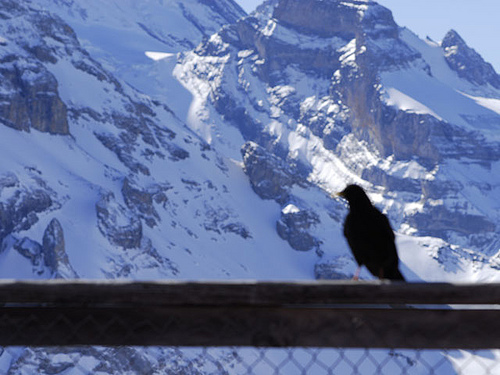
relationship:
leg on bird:
[353, 265, 361, 276] [338, 175, 418, 269]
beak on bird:
[335, 192, 340, 196] [322, 185, 415, 294]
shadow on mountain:
[110, 73, 210, 173] [75, 30, 491, 242]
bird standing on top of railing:
[333, 180, 409, 283] [0, 278, 484, 351]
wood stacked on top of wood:
[1, 278, 484, 306] [1, 304, 484, 349]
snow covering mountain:
[1, 1, 484, 371] [1, 2, 483, 371]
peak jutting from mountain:
[191, 1, 420, 88] [1, 2, 483, 371]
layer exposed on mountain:
[204, 18, 420, 213] [1, 2, 483, 371]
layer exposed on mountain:
[228, 18, 339, 76] [1, 2, 483, 371]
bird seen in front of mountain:
[333, 183, 408, 283] [1, 2, 483, 371]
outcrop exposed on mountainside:
[2, 165, 51, 243] [2, 2, 484, 372]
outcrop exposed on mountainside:
[40, 215, 78, 277] [2, 2, 484, 372]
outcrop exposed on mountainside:
[89, 185, 144, 247] [2, 2, 484, 372]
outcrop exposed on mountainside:
[1, 38, 71, 136] [2, 2, 484, 372]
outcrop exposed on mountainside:
[119, 173, 163, 228] [2, 2, 484, 372]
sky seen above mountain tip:
[233, 1, 484, 70] [187, 1, 434, 86]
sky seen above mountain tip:
[233, 1, 484, 70] [438, 26, 485, 86]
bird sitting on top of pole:
[333, 180, 409, 283] [1, 276, 484, 349]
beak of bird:
[335, 192, 340, 196] [333, 180, 409, 283]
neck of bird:
[338, 194, 372, 207] [333, 180, 409, 283]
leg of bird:
[350, 260, 365, 285] [334, 183, 405, 291]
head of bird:
[338, 181, 365, 200] [334, 183, 405, 291]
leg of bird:
[353, 265, 361, 276] [334, 183, 405, 291]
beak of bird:
[335, 192, 340, 196] [334, 183, 405, 291]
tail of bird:
[384, 267, 405, 285] [334, 181, 414, 291]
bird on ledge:
[333, 180, 409, 283] [8, 274, 484, 303]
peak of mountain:
[435, 26, 462, 46] [16, 10, 473, 262]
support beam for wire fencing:
[13, 302, 483, 347] [8, 328, 473, 373]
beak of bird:
[336, 188, 344, 198] [339, 182, 402, 287]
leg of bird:
[353, 265, 361, 276] [338, 182, 415, 287]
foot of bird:
[341, 272, 365, 284] [338, 182, 415, 287]